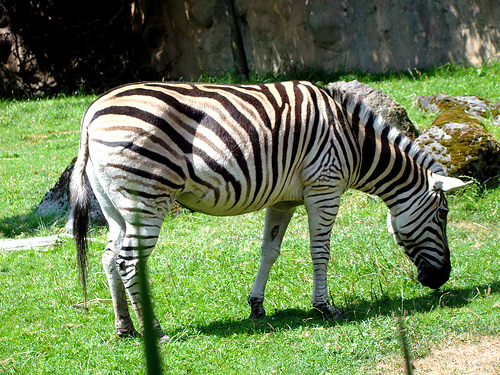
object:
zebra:
[69, 79, 473, 338]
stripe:
[291, 80, 302, 204]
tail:
[69, 119, 91, 304]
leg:
[305, 180, 340, 317]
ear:
[435, 174, 475, 193]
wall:
[1, 0, 498, 99]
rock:
[408, 94, 498, 183]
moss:
[434, 98, 491, 169]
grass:
[376, 337, 498, 374]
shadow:
[268, 283, 499, 336]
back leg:
[92, 190, 173, 339]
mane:
[317, 86, 443, 174]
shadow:
[0, 0, 170, 98]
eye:
[440, 208, 449, 215]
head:
[387, 173, 453, 289]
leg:
[246, 200, 294, 319]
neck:
[348, 107, 434, 207]